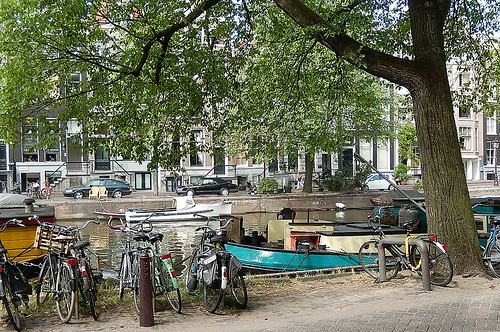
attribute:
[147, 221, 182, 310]
bicycle — green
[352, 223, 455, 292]
bicycle — black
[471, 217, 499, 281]
bicycle — blue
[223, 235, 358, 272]
boat — blue, white, green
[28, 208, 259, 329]
bikes — parked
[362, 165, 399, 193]
car — white, black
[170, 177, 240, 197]
car — black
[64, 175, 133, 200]
van — dark blue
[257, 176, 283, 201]
plant — green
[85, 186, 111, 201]
seats — light yellow